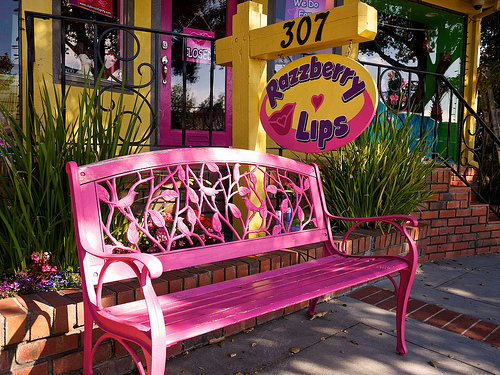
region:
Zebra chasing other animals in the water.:
[152, 297, 178, 369]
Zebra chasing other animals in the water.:
[226, 333, 227, 371]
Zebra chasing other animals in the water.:
[4, 281, 58, 310]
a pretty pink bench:
[16, 15, 462, 322]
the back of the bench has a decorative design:
[66, 134, 363, 247]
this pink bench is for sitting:
[71, 141, 436, 357]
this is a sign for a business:
[210, 10, 416, 153]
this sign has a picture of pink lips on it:
[245, 41, 387, 163]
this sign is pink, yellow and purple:
[238, 57, 376, 159]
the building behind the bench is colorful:
[33, 5, 256, 154]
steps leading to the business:
[388, 62, 499, 265]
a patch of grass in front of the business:
[317, 140, 427, 232]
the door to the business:
[151, 1, 234, 142]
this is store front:
[18, 19, 444, 316]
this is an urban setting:
[31, 68, 272, 248]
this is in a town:
[35, 32, 440, 370]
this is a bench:
[57, 130, 362, 330]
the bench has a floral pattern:
[116, 180, 292, 280]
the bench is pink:
[42, 153, 298, 305]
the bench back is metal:
[65, 150, 263, 230]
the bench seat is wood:
[175, 266, 348, 302]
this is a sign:
[233, 33, 393, 156]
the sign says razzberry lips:
[258, 36, 413, 194]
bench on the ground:
[33, 139, 453, 368]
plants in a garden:
[296, 106, 419, 231]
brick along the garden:
[6, 281, 331, 361]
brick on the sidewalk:
[372, 285, 491, 342]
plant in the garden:
[2, 91, 159, 257]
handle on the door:
[158, 50, 173, 85]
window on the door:
[171, 6, 221, 136]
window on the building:
[66, 6, 121, 71]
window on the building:
[363, 0, 460, 148]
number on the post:
[276, 13, 336, 47]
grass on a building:
[17, 205, 43, 252]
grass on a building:
[48, 159, 62, 209]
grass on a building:
[54, 113, 91, 153]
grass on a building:
[351, 167, 374, 213]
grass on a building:
[335, 184, 350, 213]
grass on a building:
[377, 147, 424, 199]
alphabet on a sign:
[263, 73, 285, 103]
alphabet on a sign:
[289, 105, 316, 142]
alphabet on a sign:
[306, 116, 324, 143]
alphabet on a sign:
[314, 116, 337, 162]